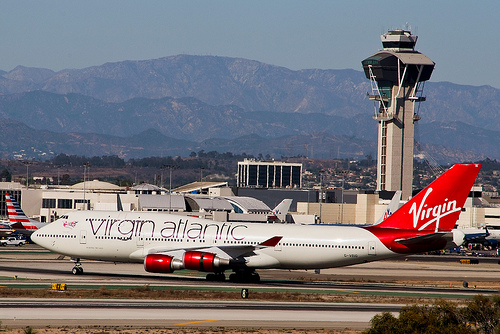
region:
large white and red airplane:
[33, 148, 479, 265]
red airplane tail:
[393, 155, 480, 261]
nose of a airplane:
[31, 201, 123, 268]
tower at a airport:
[365, 60, 428, 199]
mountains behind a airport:
[45, 60, 377, 213]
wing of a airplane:
[168, 215, 302, 281]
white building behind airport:
[236, 152, 314, 191]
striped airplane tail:
[4, 193, 31, 228]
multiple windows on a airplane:
[58, 230, 254, 247]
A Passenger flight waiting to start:
[34, 159, 499, 271]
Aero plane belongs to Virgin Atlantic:
[29, 145, 482, 286]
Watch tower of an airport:
[361, 17, 427, 209]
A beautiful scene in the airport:
[4, 19, 493, 326]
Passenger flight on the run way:
[19, 146, 495, 290]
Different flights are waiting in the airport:
[6, 141, 495, 331]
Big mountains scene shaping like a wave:
[6, 41, 496, 181]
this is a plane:
[28, 134, 488, 306]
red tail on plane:
[359, 154, 487, 261]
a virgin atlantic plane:
[14, 132, 497, 301]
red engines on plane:
[118, 234, 225, 279]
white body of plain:
[33, 195, 387, 293]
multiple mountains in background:
[3, 44, 473, 175]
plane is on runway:
[0, 152, 499, 321]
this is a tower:
[354, 24, 444, 208]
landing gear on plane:
[48, 251, 90, 282]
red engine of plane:
[175, 248, 222, 263]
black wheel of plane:
[71, 266, 78, 273]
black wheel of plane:
[208, 272, 224, 282]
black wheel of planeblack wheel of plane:
[232, 271, 262, 283]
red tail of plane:
[368, 167, 483, 252]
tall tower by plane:
[365, 27, 437, 194]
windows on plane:
[38, 231, 79, 238]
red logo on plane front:
[61, 218, 80, 228]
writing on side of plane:
[88, 212, 247, 240]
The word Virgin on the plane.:
[412, 195, 464, 233]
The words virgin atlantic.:
[85, 218, 252, 252]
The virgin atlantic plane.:
[30, 157, 488, 289]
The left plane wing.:
[142, 236, 244, 273]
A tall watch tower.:
[363, 28, 423, 215]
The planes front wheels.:
[69, 261, 84, 283]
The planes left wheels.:
[207, 270, 222, 291]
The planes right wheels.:
[237, 268, 263, 286]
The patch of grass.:
[363, 290, 495, 332]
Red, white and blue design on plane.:
[5, 188, 47, 240]